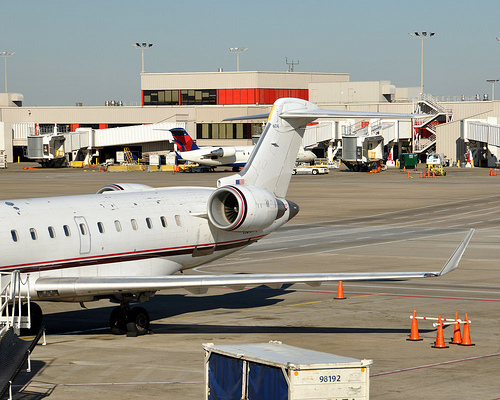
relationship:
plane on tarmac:
[0, 98, 479, 336] [2, 161, 499, 399]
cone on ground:
[408, 308, 423, 342] [3, 160, 499, 397]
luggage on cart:
[209, 358, 290, 399] [204, 341, 376, 400]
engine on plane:
[205, 185, 285, 230] [0, 98, 479, 336]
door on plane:
[75, 214, 91, 256] [0, 98, 479, 336]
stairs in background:
[414, 95, 452, 158] [0, 2, 497, 197]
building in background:
[0, 72, 498, 166] [0, 2, 497, 197]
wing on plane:
[16, 228, 473, 299] [0, 98, 479, 336]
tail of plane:
[171, 125, 202, 153] [164, 123, 318, 174]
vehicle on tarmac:
[293, 161, 328, 176] [2, 161, 499, 399]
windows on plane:
[6, 214, 194, 240] [0, 98, 479, 336]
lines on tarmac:
[282, 289, 497, 311] [2, 161, 499, 399]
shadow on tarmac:
[26, 284, 447, 336] [2, 161, 499, 399]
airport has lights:
[0, 54, 500, 398] [409, 27, 444, 41]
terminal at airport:
[139, 73, 355, 110] [0, 54, 500, 398]